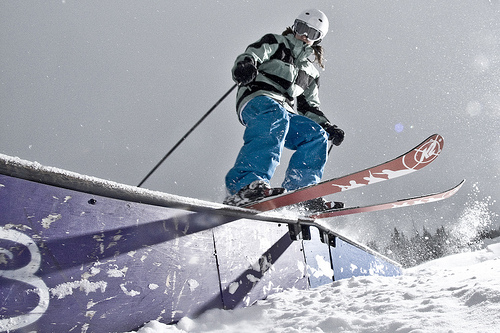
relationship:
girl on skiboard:
[254, 7, 338, 70] [275, 137, 468, 232]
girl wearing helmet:
[254, 7, 338, 70] [294, 6, 334, 34]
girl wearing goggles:
[254, 7, 338, 70] [289, 18, 326, 51]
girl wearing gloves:
[254, 7, 338, 70] [227, 61, 346, 146]